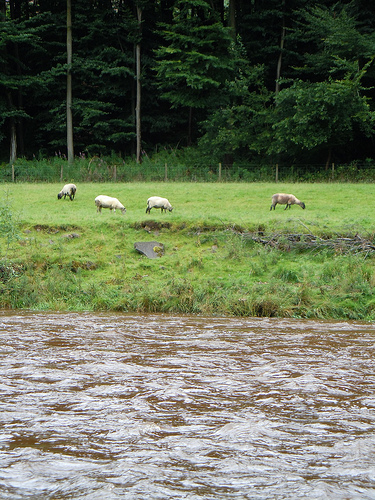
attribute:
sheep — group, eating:
[43, 164, 276, 213]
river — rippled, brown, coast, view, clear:
[73, 332, 120, 350]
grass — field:
[200, 190, 235, 213]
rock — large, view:
[128, 247, 158, 260]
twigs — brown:
[208, 247, 254, 283]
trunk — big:
[124, 155, 151, 167]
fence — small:
[172, 161, 240, 188]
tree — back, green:
[137, 27, 186, 93]